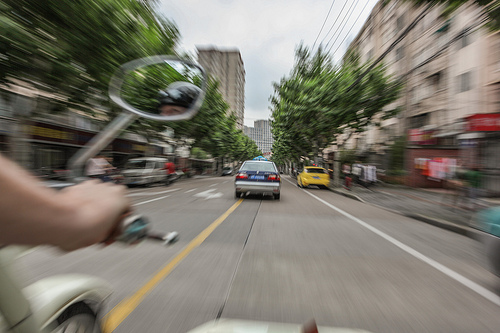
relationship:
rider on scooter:
[2, 136, 137, 259] [2, 47, 384, 331]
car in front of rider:
[229, 156, 287, 203] [0, 128, 140, 270]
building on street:
[339, 1, 484, 188] [1, 158, 481, 331]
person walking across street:
[156, 150, 178, 187] [1, 158, 481, 331]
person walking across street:
[81, 146, 124, 184] [1, 158, 481, 331]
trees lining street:
[291, 68, 366, 170] [267, 186, 377, 266]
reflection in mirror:
[142, 77, 201, 121] [105, 61, 218, 118]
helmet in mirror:
[133, 75, 215, 123] [58, 52, 238, 135]